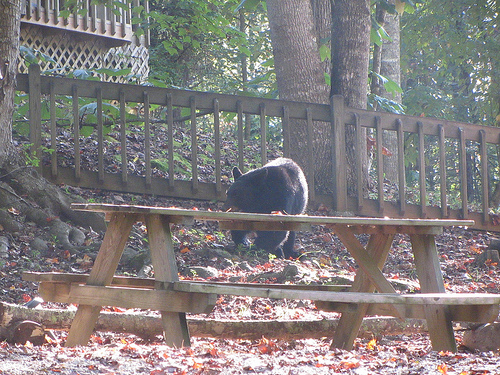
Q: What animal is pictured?
A: Brown bear.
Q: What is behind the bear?
A: Wood fence.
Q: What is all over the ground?
A: Leaves.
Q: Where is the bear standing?
A: Between the table and fence.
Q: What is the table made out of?
A: Wood.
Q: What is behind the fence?
A: Tree trunk.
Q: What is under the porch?
A: A lattice.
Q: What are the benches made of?
A: Wood.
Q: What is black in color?
A: A Bear.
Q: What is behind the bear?
A: A wooden fence.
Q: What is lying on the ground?
A: Colored leaves.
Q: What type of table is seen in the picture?
A: A wooden table.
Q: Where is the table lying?
A: In a forest.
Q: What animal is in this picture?
A: Bear.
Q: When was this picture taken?
A: During the day.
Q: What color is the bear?
A: Black.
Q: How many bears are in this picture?
A: One.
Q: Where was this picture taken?
A: In backyard.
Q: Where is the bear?
A: Behind the table.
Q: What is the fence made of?
A: Wood.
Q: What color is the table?
A: Brown.